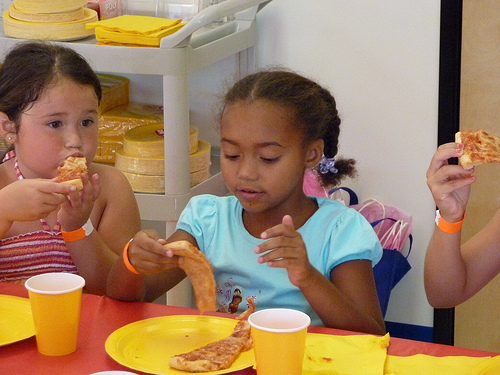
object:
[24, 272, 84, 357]
cup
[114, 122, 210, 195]
paper plates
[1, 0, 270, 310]
cart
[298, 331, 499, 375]
napkin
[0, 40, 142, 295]
child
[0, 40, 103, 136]
hair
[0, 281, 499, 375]
tablecloth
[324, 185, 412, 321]
bags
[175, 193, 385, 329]
shirt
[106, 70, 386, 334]
child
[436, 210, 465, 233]
band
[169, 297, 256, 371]
pizza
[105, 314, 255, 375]
plate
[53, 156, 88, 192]
pizza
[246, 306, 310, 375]
cup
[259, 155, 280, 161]
eye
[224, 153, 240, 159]
eye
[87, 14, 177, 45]
napkins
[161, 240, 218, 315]
pizza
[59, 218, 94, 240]
band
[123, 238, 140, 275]
bracelet